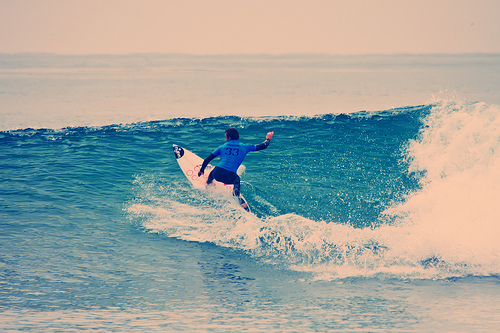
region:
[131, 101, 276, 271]
A man is on the water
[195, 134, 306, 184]
The man is wearing a blue shirt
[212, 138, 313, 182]
The man has numbers on his shirt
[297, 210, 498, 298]
The waves are white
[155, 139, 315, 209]
the surfboard is white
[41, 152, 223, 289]
The water was blue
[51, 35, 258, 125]
The sky is clear and calm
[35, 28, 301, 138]
Water is in the background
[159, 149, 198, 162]
The surfboard has a black tip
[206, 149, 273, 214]
The man is wearing swim pants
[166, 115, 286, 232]
A man on a surfboard.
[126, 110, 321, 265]
Man surfing a wave.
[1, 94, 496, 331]
The blue water of the ocean.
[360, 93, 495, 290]
A crashing wave.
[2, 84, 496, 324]
A surfer riding a wave.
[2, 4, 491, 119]
A hazy, foggy day.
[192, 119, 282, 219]
Man wearing a blue shirt.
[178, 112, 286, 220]
A male wearing a blue shirt with the number 33.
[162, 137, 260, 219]
A white surfboard.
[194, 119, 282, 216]
A man with his arm raised.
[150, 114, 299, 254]
a man surfing in the ocean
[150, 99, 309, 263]
a man surfing in the water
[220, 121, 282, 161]
a man with his arm stretched out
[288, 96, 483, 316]
a large wave in the ocean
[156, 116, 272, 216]
a man riding a surf board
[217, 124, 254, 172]
a man wearing a blue shirt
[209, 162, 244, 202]
a man wearing blue pants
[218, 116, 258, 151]
a man with dark hair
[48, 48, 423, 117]
a large body of water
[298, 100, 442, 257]
the blue water of the ocean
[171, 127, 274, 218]
Man on a surfboard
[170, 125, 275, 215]
Man surfing in the ocean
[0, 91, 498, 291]
Blue ocean wave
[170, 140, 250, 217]
White pointed surfboard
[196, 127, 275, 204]
Man wearing blue swim gear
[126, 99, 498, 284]
White ocean sea foam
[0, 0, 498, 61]
Pink ocean horizon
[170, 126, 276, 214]
Man in blue on a surfboard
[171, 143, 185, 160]
Blue circle on a surfboard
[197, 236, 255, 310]
Reflection on the water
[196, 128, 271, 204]
surfer wearing blue and black wetsuit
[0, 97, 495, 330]
wave in ocean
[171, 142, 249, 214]
white surfboard in ocean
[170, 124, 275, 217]
surfer on a surfboard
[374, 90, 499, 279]
whitecap from ocean wave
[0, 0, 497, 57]
hazy sky above horizon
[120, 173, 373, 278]
wake created by surfer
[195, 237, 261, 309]
reflection of surfer in water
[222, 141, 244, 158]
number on surfer's shirt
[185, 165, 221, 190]
red writing on white surfboard